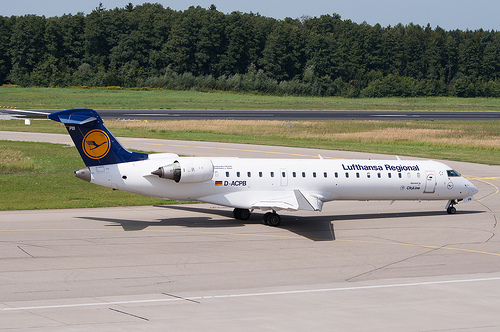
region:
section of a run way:
[281, 112, 319, 117]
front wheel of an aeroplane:
[448, 205, 456, 209]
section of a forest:
[218, 24, 282, 45]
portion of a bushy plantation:
[260, 78, 306, 90]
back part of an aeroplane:
[82, 169, 124, 181]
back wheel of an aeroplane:
[268, 215, 277, 221]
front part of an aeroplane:
[463, 180, 477, 194]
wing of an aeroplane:
[298, 198, 308, 208]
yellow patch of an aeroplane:
[91, 136, 104, 148]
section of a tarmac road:
[179, 236, 274, 303]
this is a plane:
[6, 105, 469, 268]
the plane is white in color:
[37, 108, 491, 265]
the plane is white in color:
[55, 153, 482, 216]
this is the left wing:
[264, 183, 323, 223]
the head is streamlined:
[443, 162, 482, 207]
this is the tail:
[47, 101, 132, 196]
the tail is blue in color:
[57, 104, 118, 161]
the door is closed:
[280, 168, 285, 185]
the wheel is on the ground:
[442, 205, 464, 214]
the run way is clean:
[7, 234, 453, 329]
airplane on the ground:
[31, 85, 488, 250]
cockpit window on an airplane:
[443, 164, 465, 181]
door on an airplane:
[419, 167, 441, 197]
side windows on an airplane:
[288, 167, 330, 183]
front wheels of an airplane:
[443, 194, 460, 219]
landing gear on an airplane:
[224, 201, 285, 231]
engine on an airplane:
[144, 153, 219, 188]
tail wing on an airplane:
[38, 101, 154, 171]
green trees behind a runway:
[3, 0, 498, 103]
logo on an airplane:
[72, 126, 115, 163]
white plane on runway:
[48, 105, 485, 227]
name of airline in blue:
[333, 156, 426, 186]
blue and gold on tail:
[52, 109, 133, 169]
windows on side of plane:
[283, 164, 345, 183]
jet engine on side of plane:
[148, 154, 220, 191]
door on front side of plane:
[417, 166, 439, 198]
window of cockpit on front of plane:
[442, 165, 461, 185]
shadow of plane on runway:
[86, 209, 342, 244]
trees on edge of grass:
[227, 21, 358, 106]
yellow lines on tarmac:
[475, 167, 496, 192]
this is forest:
[96, 8, 460, 92]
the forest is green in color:
[138, 18, 469, 87]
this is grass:
[208, 94, 313, 108]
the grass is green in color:
[164, 88, 264, 105]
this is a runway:
[138, 103, 416, 125]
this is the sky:
[392, 1, 442, 19]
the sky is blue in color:
[396, 1, 476, 17]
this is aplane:
[18, 101, 464, 242]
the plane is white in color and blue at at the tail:
[34, 96, 480, 243]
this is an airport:
[1, 47, 486, 319]